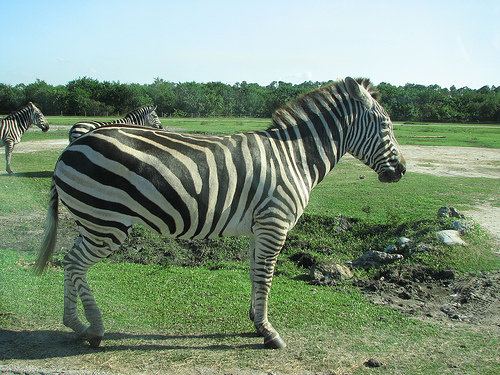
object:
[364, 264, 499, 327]
dirt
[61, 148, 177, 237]
stripes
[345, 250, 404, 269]
rock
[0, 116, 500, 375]
ground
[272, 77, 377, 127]
mane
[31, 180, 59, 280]
tail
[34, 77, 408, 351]
zebra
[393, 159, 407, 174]
nose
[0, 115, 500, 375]
grass